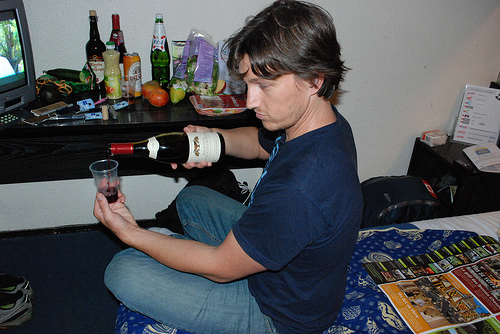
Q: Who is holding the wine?
A: A man.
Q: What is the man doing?
A: Pouring wine.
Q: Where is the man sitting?
A: On the floor.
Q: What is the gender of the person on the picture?
A: Male.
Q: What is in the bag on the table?
A: Salad.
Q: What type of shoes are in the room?
A: Sneakers.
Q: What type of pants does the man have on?
A: Jeans.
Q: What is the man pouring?
A: Wine.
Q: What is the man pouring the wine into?
A: Cup.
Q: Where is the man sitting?
A: On bed.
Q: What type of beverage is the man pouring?
A: Wine.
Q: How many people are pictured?
A: One.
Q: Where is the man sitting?
A: On a bed.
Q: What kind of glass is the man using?
A: A plastic glass.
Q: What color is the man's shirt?
A: Blue.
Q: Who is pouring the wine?
A: The man.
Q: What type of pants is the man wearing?
A: Blue jeans.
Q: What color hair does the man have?
A: Brown.